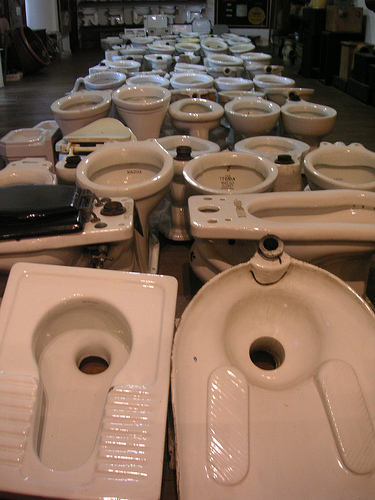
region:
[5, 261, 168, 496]
white ceramic plate on table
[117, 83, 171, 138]
white ceramic bowl on table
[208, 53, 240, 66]
dinner bowl on table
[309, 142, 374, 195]
white bowl on table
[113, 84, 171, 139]
white flower pot on table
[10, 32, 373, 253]
bowls sitting on table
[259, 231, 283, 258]
grey metal washer on bowl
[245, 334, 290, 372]
hole in ceramic bowl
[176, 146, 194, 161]
black bolt on bowl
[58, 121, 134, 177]
bowl with lid on table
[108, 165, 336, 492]
the toilets are white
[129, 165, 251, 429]
the toilets are white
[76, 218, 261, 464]
the toilets are white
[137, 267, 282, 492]
the toilets are white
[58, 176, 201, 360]
the toilets are white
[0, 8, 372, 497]
toilet bowls in many shapes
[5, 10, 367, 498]
toilet bowls in many sizes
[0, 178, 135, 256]
Toilet with black lid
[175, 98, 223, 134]
White toilet bowl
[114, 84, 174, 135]
tall white toilet bowl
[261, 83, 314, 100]
Cream colored toilet bowl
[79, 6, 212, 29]
Toilet bowls on wall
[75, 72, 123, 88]
Round toilet bowl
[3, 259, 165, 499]
white toilet bowl with hole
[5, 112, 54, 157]
White toilet bowl on floor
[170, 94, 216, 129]
variety of white toilets in room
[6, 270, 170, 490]
variety of white toilets in room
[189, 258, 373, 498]
variety of white toilets in room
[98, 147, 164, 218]
variety of white toilets in room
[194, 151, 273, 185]
variety of white toilets in room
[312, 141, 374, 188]
variety of white toilets in room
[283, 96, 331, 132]
variety of white toilets in room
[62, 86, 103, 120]
variety of white toilets in room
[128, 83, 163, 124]
variety of white toilets in room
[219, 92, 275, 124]
variety of white toilets in room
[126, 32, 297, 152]
the toilet bowl is white